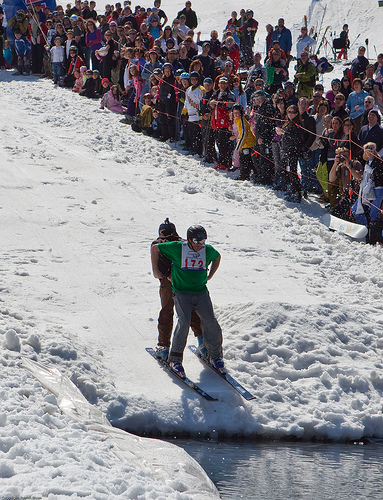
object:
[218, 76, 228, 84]
cap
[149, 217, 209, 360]
people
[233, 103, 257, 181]
boy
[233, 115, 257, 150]
jacket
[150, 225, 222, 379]
man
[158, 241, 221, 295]
shirt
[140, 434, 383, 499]
water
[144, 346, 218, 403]
skis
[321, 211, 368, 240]
snowboard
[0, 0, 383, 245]
crowd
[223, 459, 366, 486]
ripples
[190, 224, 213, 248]
helmet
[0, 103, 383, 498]
snow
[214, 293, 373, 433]
snow pile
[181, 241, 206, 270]
bib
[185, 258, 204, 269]
172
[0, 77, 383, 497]
ground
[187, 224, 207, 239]
helmet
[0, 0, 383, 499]
photo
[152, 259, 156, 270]
skinned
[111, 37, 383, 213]
rope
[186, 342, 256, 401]
skis